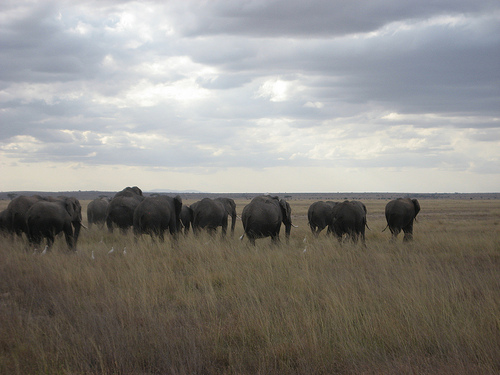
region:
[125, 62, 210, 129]
white clouds in blue sky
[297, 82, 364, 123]
white clouds in blue sky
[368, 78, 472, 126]
white clouds in blue sky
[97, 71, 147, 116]
white clouds in blue sky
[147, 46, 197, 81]
white clouds in blue sky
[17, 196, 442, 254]
brown cows in field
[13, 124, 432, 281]
A group of elephants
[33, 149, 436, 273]
The elephants are walking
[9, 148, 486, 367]
The elephants are in a grass field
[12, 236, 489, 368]
The grass is very tall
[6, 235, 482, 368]
The grass is brown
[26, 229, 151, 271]
White birds in the grass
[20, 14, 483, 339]
Picture was taken outside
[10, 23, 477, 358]
The elephants are in nature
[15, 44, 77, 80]
white clouds in blue sky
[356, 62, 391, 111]
white clouds in blue sky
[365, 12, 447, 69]
white clouds in blue sky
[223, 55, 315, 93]
white clouds in blue sky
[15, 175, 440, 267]
brown cows in field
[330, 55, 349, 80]
white clouds in blue sky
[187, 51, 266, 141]
white clouds in blue sky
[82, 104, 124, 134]
white clouds in blue sky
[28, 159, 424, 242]
Elephants walking in the field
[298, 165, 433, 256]
Elephants walking in the field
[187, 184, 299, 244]
Elephants walking in the field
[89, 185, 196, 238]
Elephants walking in the field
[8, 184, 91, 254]
Elephants walking in the field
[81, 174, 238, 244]
Elephants walking in the field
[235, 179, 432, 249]
Elephants walking in the field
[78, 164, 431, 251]
Elephants walking in the field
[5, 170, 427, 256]
Elephants walking in the field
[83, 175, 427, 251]
Elephants walking in the field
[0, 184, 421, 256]
a herd of elephants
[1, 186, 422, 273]
elephants walking in tall grass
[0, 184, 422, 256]
a herd of dark gray elephants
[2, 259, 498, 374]
tall brown grass on the ground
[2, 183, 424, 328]
elephants on a safari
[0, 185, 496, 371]
a herd of elephants walking to the other side of the field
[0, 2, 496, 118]
stormy clouds in the sky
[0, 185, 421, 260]
elephants migrating to another location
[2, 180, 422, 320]
elephants walking in a wildlife park